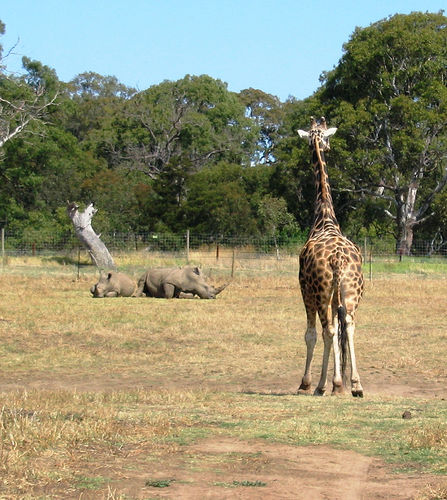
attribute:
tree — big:
[346, 50, 414, 132]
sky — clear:
[0, 1, 445, 99]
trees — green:
[18, 64, 320, 252]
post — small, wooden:
[2, 224, 11, 267]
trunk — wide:
[395, 184, 418, 255]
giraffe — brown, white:
[277, 115, 368, 399]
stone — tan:
[397, 399, 439, 429]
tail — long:
[319, 259, 356, 327]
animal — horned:
[93, 265, 231, 300]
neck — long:
[305, 144, 341, 231]